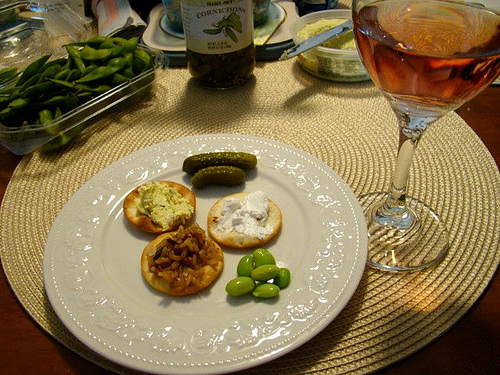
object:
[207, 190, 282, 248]
cracker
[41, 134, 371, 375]
plate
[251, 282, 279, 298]
lima bean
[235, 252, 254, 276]
lima bean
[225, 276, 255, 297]
bean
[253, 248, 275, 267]
bean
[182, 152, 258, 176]
pickles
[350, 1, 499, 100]
wine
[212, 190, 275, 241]
cheese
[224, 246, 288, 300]
food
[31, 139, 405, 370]
white plate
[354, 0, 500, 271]
glass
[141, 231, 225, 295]
cracker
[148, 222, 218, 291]
rice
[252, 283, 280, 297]
bean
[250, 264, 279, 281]
bean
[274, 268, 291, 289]
bean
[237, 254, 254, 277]
bean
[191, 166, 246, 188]
pickle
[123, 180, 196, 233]
crackers